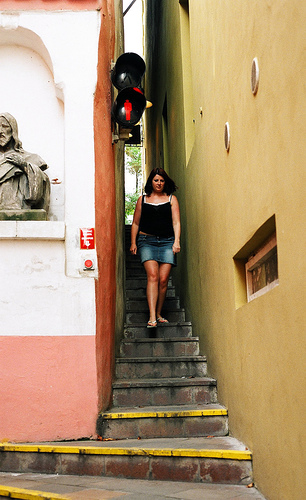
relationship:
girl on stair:
[130, 168, 181, 329] [109, 378, 218, 409]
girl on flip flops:
[130, 168, 181, 329] [146, 319, 156, 329]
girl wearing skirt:
[130, 168, 181, 329] [139, 230, 177, 265]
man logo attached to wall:
[124, 99, 132, 120] [106, 1, 125, 407]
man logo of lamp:
[124, 99, 132, 120] [104, 53, 150, 146]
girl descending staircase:
[130, 168, 181, 329] [99, 221, 254, 494]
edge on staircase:
[104, 411, 228, 417] [0, 225, 265, 498]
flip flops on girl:
[147, 319, 158, 328] [131, 170, 180, 331]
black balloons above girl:
[108, 42, 155, 135] [129, 175, 181, 334]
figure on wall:
[0, 112, 51, 222] [2, 3, 117, 451]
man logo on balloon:
[121, 97, 134, 125] [110, 89, 150, 132]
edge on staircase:
[99, 408, 239, 423] [110, 310, 252, 500]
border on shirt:
[140, 187, 173, 207] [134, 190, 181, 246]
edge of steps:
[98, 406, 258, 468] [11, 405, 265, 494]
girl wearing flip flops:
[130, 168, 181, 329] [144, 313, 172, 330]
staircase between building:
[110, 310, 200, 477] [6, 2, 130, 454]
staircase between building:
[110, 310, 200, 477] [139, 2, 293, 498]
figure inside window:
[0, 108, 53, 222] [2, 23, 61, 233]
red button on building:
[75, 257, 102, 276] [1, 0, 300, 498]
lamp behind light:
[104, 40, 163, 145] [112, 92, 150, 150]